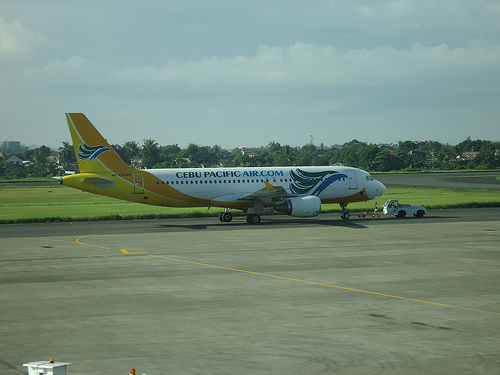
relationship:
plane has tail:
[55, 110, 386, 227] [49, 110, 136, 201]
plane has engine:
[55, 110, 386, 227] [272, 190, 323, 221]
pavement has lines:
[1, 206, 499, 373] [0, 231, 498, 319]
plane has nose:
[55, 110, 386, 227] [373, 175, 387, 201]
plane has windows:
[55, 110, 386, 227] [270, 176, 276, 184]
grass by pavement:
[0, 171, 499, 221] [1, 206, 499, 373]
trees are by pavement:
[0, 136, 498, 177] [1, 206, 499, 373]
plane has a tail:
[55, 110, 386, 227] [49, 110, 136, 201]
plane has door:
[55, 110, 386, 227] [345, 166, 359, 190]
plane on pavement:
[55, 110, 386, 227] [1, 206, 499, 373]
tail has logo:
[49, 110, 136, 201] [78, 142, 109, 165]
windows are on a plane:
[270, 176, 276, 184] [55, 110, 386, 227]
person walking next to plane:
[371, 203, 380, 217] [55, 110, 386, 227]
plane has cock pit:
[55, 110, 386, 227] [356, 168, 374, 182]